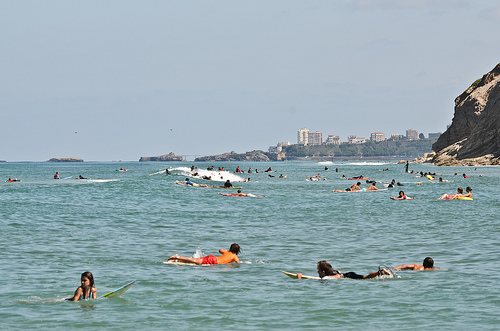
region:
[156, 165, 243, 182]
white wave crest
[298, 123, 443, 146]
building in the background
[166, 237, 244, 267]
guy in red swim trunks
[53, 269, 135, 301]
girl with blue and green surfboard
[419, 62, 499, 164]
large rock cliff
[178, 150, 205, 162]
faint bringe to island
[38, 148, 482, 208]
many people in the ocean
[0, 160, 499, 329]
relatively calm blue ocean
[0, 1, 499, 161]
gray and blue sky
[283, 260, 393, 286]
guy wearing black with a surfboard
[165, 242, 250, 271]
man with red swim trunks on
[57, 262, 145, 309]
girl on a surfboard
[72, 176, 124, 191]
a wave in the ocean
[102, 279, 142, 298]
green and blue surf board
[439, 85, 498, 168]
a rocky cliff leading to the ocean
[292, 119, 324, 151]
a large building near the shore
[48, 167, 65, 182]
a person sitting on a surfboard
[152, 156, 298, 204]
a group of people in the ocean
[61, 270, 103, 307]
a girl looking over her shoulder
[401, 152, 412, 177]
someone standing in the ocean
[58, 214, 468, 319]
People in ocean swimming and surfing.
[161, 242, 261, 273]
Boy wearing red swim trunks on surfboard.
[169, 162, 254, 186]
People on crest of wave.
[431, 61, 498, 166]
Edge of rock cliff on hill near water.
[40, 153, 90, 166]
Island rock formation in water.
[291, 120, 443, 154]
City in distance next to ocean.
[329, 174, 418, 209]
People floating on top of surfboards.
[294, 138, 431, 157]
Trees growing next to ocean in distance.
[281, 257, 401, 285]
Man holding on to surfboard person is floating on.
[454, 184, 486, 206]
Woman floating in water on yellow inner tube.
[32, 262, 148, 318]
Girl on a surfboard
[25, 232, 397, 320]
Three people floating on surfboards in the ocean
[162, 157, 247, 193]
People riding on a small wave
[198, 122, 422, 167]
Buildings above the coastline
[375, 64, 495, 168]
Rocky outcrop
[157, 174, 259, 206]
People paddling out to catch a wave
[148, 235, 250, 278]
Boy in orange and red on a surfboard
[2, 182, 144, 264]
Calm blue and green ocean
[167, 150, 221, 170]
Bridge from mainland to an island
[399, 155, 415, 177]
Man standing in shallow water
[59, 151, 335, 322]
people are swimming in the beach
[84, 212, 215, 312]
people are swimming in the beach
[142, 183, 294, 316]
people are swimming in the beach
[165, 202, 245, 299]
people are swimming in the beach